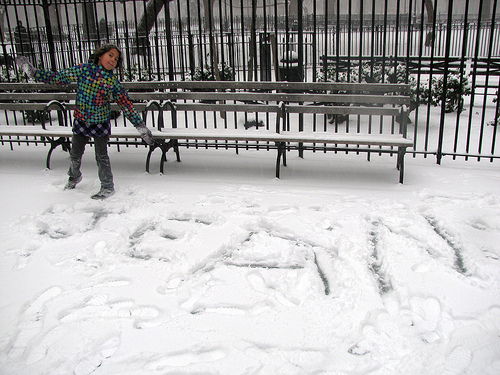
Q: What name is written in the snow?
A: Jean.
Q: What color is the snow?
A: White.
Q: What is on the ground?
A: Snow.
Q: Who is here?
A: A girl.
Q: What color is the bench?
A: Gray.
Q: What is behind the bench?
A: Fence.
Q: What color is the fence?
A: Black.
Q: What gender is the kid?
A: Female.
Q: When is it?
A: During the day time.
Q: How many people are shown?
A: 1.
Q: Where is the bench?
A: Behind girl.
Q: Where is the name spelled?
A: In snow.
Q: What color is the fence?
A: Black.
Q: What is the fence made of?
A: Metal.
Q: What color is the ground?
A: White.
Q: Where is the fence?
A: Behind bench.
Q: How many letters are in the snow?
A: 4.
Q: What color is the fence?
A: Grey.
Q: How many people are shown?
A: One.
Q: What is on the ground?
A: Snow.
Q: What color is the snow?
A: White.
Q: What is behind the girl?
A: A bench.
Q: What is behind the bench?
A: A fence.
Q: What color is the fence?
A: Black.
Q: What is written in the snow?
A: Jean.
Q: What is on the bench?
A: Snow.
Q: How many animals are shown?
A: Zero.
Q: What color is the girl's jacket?
A: Blue.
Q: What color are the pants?
A: Black.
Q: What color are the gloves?
A: Black.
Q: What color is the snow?
A: White.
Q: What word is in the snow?
A: Jean.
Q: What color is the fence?
A: Black.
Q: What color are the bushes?
A: Green.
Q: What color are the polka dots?
A: White.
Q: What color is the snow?
A: White.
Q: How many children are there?
A: One.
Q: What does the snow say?
A: JEAN.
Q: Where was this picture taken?
A: In the park.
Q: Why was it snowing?
A: Because it was cold.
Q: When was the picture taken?
A: Winter.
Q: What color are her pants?
A: Black.